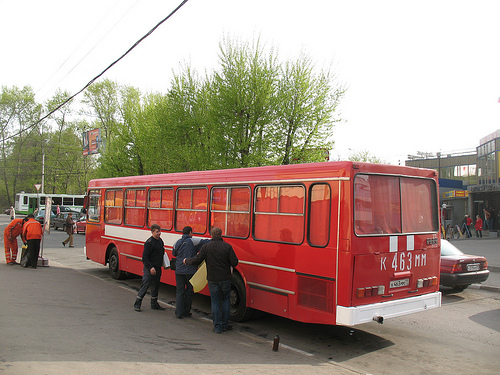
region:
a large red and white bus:
[75, 163, 446, 319]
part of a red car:
[435, 237, 489, 290]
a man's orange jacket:
[20, 215, 38, 238]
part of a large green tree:
[154, 38, 332, 166]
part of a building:
[402, 137, 498, 197]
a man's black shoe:
[150, 297, 165, 310]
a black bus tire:
[100, 246, 121, 274]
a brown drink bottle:
[271, 330, 281, 352]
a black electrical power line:
[2, 0, 195, 158]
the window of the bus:
[101, 188, 122, 224]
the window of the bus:
[125, 188, 147, 226]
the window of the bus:
[147, 186, 174, 228]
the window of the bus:
[177, 188, 207, 235]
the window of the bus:
[210, 185, 250, 239]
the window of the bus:
[252, 182, 304, 244]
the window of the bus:
[306, 181, 330, 248]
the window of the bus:
[353, 172, 436, 235]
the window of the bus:
[91, 190, 100, 217]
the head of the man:
[152, 223, 159, 237]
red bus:
[50, 158, 445, 326]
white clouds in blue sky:
[414, 39, 451, 53]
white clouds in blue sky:
[368, 38, 415, 73]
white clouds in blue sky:
[377, 86, 459, 120]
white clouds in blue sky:
[341, 75, 411, 147]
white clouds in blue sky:
[231, 5, 286, 29]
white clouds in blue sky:
[12, 8, 86, 48]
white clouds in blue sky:
[42, 18, 80, 53]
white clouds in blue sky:
[168, 29, 222, 66]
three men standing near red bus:
[122, 210, 254, 328]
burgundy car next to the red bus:
[432, 224, 493, 306]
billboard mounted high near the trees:
[69, 118, 123, 158]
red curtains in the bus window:
[105, 182, 143, 233]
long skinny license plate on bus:
[377, 271, 423, 293]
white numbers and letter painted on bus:
[366, 241, 440, 281]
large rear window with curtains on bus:
[352, 169, 447, 240]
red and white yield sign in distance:
[28, 174, 49, 205]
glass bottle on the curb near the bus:
[259, 326, 285, 355]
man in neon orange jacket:
[23, 209, 44, 267]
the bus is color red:
[70, 154, 454, 335]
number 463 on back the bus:
[371, 237, 435, 282]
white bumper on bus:
[334, 287, 449, 338]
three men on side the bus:
[124, 199, 256, 339]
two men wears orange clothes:
[2, 211, 49, 269]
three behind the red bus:
[66, 27, 448, 358]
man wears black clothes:
[131, 220, 168, 316]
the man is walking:
[56, 207, 83, 252]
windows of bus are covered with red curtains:
[96, 182, 338, 254]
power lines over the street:
[0, 2, 210, 155]